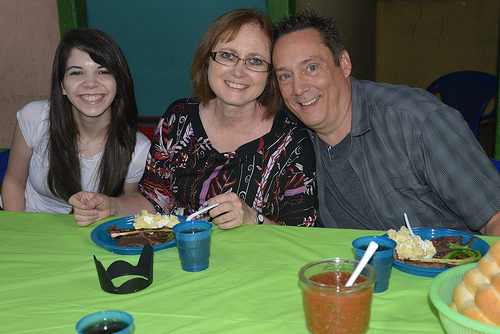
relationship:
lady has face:
[0, 28, 152, 212] [69, 76, 114, 111]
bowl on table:
[309, 266, 378, 333] [1, 220, 88, 305]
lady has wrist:
[0, 28, 152, 212] [68, 185, 112, 237]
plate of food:
[82, 208, 152, 259] [142, 202, 175, 246]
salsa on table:
[302, 301, 365, 331] [1, 220, 88, 305]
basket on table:
[447, 288, 488, 328] [1, 220, 88, 305]